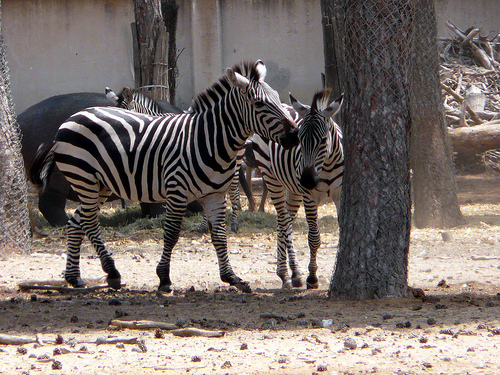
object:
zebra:
[37, 59, 305, 298]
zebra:
[246, 82, 349, 295]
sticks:
[108, 317, 227, 339]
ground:
[4, 176, 499, 374]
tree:
[325, 2, 416, 299]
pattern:
[323, 0, 416, 300]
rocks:
[20, 292, 487, 371]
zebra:
[117, 86, 172, 121]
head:
[223, 57, 302, 152]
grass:
[25, 203, 315, 245]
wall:
[1, 0, 315, 59]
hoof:
[155, 285, 173, 297]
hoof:
[232, 278, 256, 295]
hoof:
[62, 271, 87, 290]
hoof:
[102, 273, 124, 292]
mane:
[183, 58, 262, 118]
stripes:
[74, 117, 225, 191]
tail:
[27, 138, 58, 193]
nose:
[277, 124, 303, 151]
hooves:
[290, 273, 304, 290]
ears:
[222, 66, 251, 90]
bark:
[325, 1, 417, 302]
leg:
[228, 171, 244, 235]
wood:
[438, 22, 500, 124]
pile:
[441, 20, 499, 171]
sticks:
[441, 17, 500, 128]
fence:
[0, 44, 35, 258]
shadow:
[1, 291, 498, 330]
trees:
[393, 2, 479, 235]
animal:
[14, 91, 205, 230]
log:
[447, 122, 500, 155]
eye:
[251, 99, 268, 110]